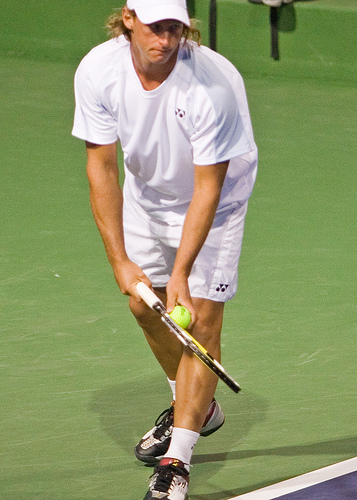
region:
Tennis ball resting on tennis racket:
[122, 274, 247, 394]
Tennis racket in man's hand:
[98, 248, 264, 396]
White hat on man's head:
[113, 10, 208, 35]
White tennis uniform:
[66, 13, 260, 317]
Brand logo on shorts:
[212, 281, 231, 296]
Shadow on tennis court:
[68, 358, 261, 496]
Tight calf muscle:
[168, 343, 197, 425]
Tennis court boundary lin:
[244, 453, 355, 498]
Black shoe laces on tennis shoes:
[149, 462, 175, 497]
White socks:
[161, 421, 209, 473]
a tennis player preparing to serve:
[42, 0, 308, 497]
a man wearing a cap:
[113, 1, 201, 74]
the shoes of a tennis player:
[130, 386, 229, 498]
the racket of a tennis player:
[136, 286, 238, 395]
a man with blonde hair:
[109, 2, 209, 76]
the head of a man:
[118, 2, 198, 80]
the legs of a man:
[125, 283, 237, 498]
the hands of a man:
[110, 255, 202, 338]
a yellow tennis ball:
[166, 303, 193, 333]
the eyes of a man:
[144, 20, 186, 32]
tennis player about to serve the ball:
[69, 0, 259, 498]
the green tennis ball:
[167, 303, 191, 330]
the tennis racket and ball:
[134, 280, 246, 397]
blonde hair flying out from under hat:
[102, 5, 204, 53]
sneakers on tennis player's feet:
[132, 396, 225, 498]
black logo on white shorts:
[213, 281, 230, 292]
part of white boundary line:
[223, 455, 354, 498]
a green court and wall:
[0, 0, 356, 498]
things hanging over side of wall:
[188, 0, 298, 63]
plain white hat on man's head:
[125, 0, 191, 28]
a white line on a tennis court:
[277, 458, 334, 494]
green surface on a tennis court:
[285, 413, 335, 446]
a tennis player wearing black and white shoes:
[124, 382, 246, 499]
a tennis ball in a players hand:
[160, 293, 199, 338]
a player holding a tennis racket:
[104, 248, 261, 405]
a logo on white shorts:
[212, 277, 231, 298]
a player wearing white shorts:
[92, 179, 266, 305]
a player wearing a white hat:
[112, 0, 200, 84]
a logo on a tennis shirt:
[169, 103, 189, 125]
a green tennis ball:
[164, 303, 191, 327]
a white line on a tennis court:
[229, 456, 355, 497]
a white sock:
[163, 425, 194, 469]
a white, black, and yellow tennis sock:
[135, 283, 239, 394]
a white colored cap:
[121, 0, 194, 25]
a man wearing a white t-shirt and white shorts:
[72, 0, 283, 496]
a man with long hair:
[70, 0, 258, 497]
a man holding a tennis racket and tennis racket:
[69, 2, 260, 498]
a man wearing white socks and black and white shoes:
[71, 1, 259, 498]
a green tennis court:
[0, 57, 355, 498]